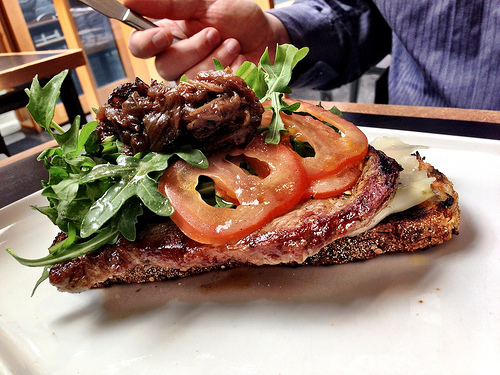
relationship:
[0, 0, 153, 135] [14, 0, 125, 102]
wooden door with glass panel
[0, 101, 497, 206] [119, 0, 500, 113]
table in front of man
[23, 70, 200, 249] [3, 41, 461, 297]
greens on meat dish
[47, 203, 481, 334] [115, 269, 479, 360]
shadow on plate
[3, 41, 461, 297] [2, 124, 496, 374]
meat dish on plate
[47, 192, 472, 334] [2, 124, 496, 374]
shadow on plate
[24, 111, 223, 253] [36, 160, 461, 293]
lettuce on meat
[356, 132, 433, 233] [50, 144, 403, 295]
cheese on bacon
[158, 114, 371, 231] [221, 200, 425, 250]
slices on top of bacon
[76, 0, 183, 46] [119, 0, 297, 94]
knife in hand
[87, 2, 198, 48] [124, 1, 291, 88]
knife in hand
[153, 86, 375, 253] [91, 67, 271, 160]
tomatoe slices on meat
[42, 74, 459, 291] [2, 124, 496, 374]
meat dish on plate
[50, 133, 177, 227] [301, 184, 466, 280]
green lettuce on meat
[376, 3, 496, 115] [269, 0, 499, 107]
stripes on shirt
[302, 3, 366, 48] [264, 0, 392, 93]
button on sleeve